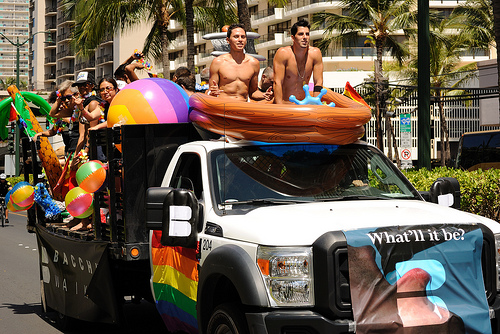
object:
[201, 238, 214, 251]
204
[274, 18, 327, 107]
guy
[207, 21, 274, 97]
guy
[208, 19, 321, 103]
2 men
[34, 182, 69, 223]
beach toys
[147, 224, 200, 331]
flag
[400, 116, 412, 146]
sign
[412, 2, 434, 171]
pole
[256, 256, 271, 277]
turn signal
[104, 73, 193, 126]
ball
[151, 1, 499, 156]
apartment buildings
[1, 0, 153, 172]
apartment buildings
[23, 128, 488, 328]
truck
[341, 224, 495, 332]
corporate logo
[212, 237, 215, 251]
sign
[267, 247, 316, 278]
headlight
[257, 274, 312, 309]
headlight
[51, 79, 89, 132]
people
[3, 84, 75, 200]
beach toys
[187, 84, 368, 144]
boat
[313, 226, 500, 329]
front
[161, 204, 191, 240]
mirror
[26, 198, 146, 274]
bed